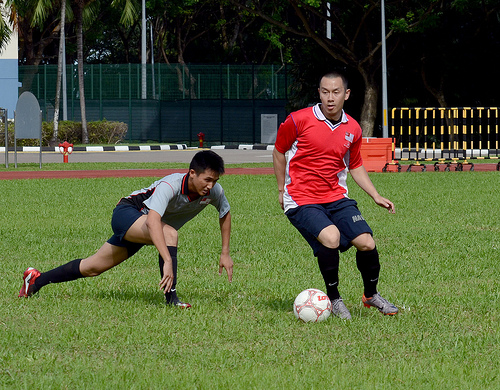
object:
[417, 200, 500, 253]
grass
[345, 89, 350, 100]
ear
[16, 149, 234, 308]
player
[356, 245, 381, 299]
socks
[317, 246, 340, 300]
socks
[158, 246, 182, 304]
socks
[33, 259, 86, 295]
socks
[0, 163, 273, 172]
grass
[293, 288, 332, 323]
ball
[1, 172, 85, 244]
grass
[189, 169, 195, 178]
ear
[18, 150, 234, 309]
man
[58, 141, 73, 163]
hydrant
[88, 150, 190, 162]
street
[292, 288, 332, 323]
soccer ball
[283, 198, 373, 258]
blue shorts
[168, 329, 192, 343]
bad sentece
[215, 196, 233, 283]
arm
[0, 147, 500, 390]
ground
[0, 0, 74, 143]
tree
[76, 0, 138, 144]
tree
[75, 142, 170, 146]
grass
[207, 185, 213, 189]
nose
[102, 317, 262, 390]
grass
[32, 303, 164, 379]
grass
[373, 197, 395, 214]
left hand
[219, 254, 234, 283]
left hand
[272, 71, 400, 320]
man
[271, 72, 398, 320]
player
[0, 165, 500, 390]
field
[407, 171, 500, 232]
grass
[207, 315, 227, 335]
grass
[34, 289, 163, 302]
shadow